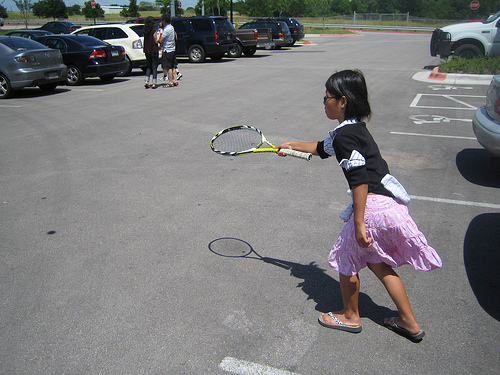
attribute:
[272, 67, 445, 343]
girl — young, little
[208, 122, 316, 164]
tennis racket — yellow black, white, black, yellow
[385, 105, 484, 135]
parking space — handicapped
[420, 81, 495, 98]
parking space — handicapped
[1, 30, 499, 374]
pavement — large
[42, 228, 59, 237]
shadow — ball shaped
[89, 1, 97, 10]
stop sign — red, white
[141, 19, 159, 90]
person — standing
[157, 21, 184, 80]
person — standing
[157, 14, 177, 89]
person — standing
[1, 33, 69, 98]
car — parked, grey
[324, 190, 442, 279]
skirt — light pink, pink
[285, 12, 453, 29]
fence — chain link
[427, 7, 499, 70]
truck — white, parked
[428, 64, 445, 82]
curb — red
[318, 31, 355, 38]
curb — red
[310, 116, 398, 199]
shirt — black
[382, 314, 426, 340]
flip flop — black, white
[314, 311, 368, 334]
flip flop — black, white